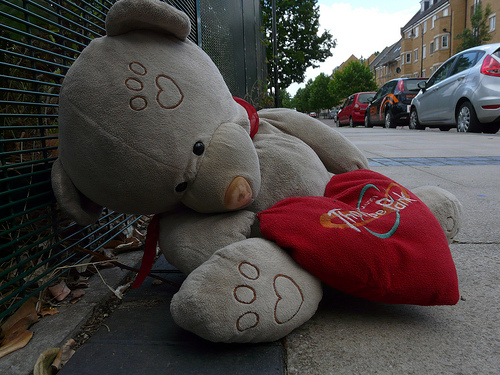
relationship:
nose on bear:
[222, 175, 259, 215] [34, 0, 467, 348]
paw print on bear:
[126, 59, 181, 118] [50, 16, 460, 350]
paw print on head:
[126, 59, 181, 118] [49, 1, 259, 225]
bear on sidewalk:
[50, 16, 460, 350] [0, 127, 499, 374]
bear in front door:
[50, 0, 462, 342] [3, 0, 145, 265]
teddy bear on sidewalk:
[50, 46, 462, 352] [312, 78, 493, 220]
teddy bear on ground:
[50, 0, 462, 344] [2, 120, 498, 370]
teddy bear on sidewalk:
[50, 0, 462, 344] [326, 303, 482, 363]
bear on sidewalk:
[50, 16, 460, 350] [58, 124, 498, 372]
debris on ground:
[15, 205, 259, 370] [2, 120, 498, 370]